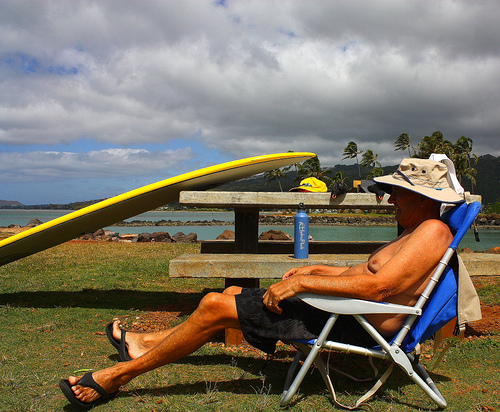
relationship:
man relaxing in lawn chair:
[68, 185, 455, 404] [279, 201, 482, 409]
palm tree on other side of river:
[266, 167, 282, 190] [1, 207, 500, 251]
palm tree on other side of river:
[299, 156, 333, 191] [1, 207, 500, 251]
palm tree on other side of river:
[343, 141, 362, 181] [1, 207, 500, 251]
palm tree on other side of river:
[361, 151, 385, 178] [1, 207, 500, 251]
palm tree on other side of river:
[395, 132, 412, 157] [1, 207, 500, 251]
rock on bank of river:
[132, 233, 152, 243] [1, 207, 500, 251]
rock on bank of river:
[151, 230, 173, 242] [1, 207, 500, 251]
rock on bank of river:
[171, 232, 184, 243] [1, 207, 500, 251]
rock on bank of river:
[188, 232, 196, 243] [1, 207, 500, 251]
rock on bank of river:
[217, 229, 236, 241] [1, 207, 500, 251]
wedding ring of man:
[266, 299, 273, 307] [68, 185, 455, 404]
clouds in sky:
[2, 1, 499, 166] [1, 0, 500, 206]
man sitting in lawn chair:
[68, 185, 455, 404] [279, 201, 482, 409]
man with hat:
[68, 185, 455, 404] [373, 159, 465, 204]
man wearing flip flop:
[68, 185, 455, 404] [59, 370, 118, 411]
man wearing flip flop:
[68, 185, 455, 404] [106, 323, 132, 361]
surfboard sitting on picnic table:
[0, 151, 314, 267] [171, 190, 499, 346]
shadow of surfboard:
[0, 289, 204, 312] [0, 151, 314, 267]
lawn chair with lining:
[279, 201, 482, 409] [282, 202, 480, 356]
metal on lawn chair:
[280, 248, 455, 408] [279, 201, 482, 409]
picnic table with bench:
[171, 190, 499, 346] [169, 252, 466, 348]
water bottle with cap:
[294, 203, 310, 259] [297, 202, 307, 210]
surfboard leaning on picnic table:
[0, 151, 314, 267] [171, 190, 499, 346]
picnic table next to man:
[171, 190, 499, 346] [68, 185, 455, 404]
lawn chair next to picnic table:
[279, 201, 482, 409] [171, 190, 499, 346]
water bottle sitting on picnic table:
[294, 203, 310, 259] [171, 190, 499, 346]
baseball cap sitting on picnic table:
[289, 176, 328, 194] [171, 190, 499, 346]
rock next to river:
[132, 233, 152, 243] [1, 207, 500, 251]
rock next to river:
[151, 230, 173, 242] [1, 207, 500, 251]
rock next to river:
[171, 232, 184, 243] [1, 207, 500, 251]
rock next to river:
[188, 232, 196, 243] [1, 207, 500, 251]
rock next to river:
[217, 229, 236, 241] [1, 207, 500, 251]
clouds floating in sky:
[2, 1, 499, 166] [1, 0, 500, 206]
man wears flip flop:
[68, 185, 455, 404] [59, 370, 118, 411]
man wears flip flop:
[68, 185, 455, 404] [106, 323, 132, 361]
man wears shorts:
[68, 185, 455, 404] [234, 286, 377, 355]